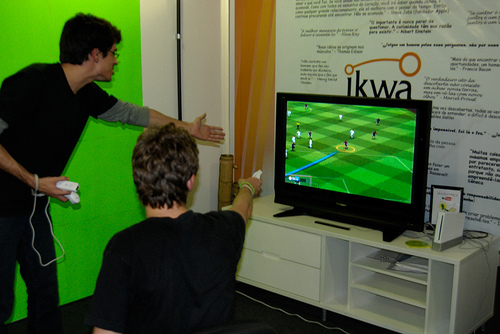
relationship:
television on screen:
[271, 87, 431, 242] [284, 100, 416, 205]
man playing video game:
[91, 128, 261, 331] [283, 99, 417, 205]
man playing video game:
[0, 11, 226, 333] [283, 99, 417, 205]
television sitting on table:
[271, 87, 431, 242] [216, 192, 497, 332]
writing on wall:
[291, 0, 498, 232] [273, 2, 498, 244]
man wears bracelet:
[91, 128, 261, 331] [236, 178, 257, 195]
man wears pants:
[4, 1, 141, 215] [2, 197, 65, 331]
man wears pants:
[0, 11, 226, 333] [2, 194, 72, 315]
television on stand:
[271, 87, 431, 242] [216, 190, 495, 329]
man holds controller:
[0, 11, 226, 333] [55, 179, 80, 204]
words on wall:
[284, 4, 494, 109] [421, 75, 470, 98]